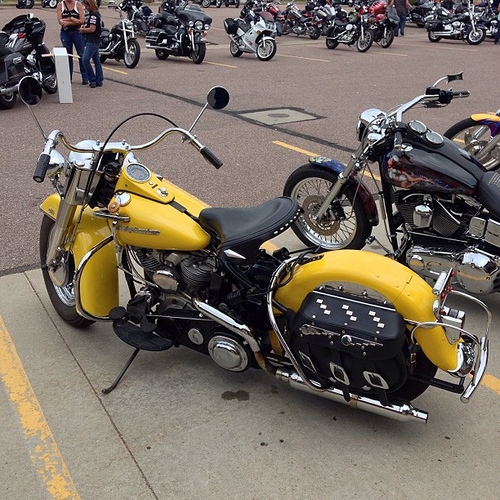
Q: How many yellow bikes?
A: Two.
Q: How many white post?
A: One.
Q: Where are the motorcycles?
A: Parking lot.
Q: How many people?
A: Three.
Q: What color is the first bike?
A: Yellow, silver, black.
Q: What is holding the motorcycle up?
A: Kickstand.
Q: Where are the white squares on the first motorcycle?
A: Side bag.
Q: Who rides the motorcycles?
A: People.